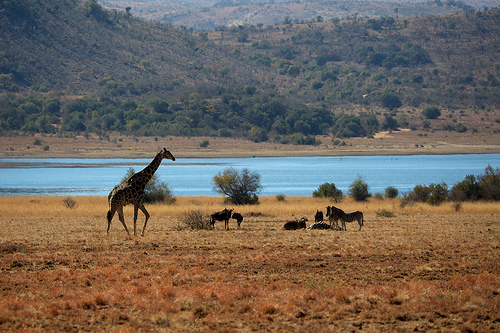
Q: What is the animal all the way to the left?
A: Giraffe.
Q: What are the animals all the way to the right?
A: Zebras.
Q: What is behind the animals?
A: A river.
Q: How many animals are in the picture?
A: 8.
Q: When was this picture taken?
A: Daytime.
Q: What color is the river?
A: Blue.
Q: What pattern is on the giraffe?
A: Spots.